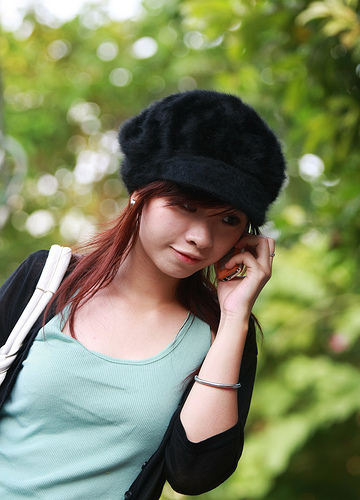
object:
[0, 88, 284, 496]
girl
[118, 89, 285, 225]
hat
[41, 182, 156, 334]
hair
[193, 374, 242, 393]
bracelet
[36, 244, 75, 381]
strap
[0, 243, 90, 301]
shoulder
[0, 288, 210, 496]
shirt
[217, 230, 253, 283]
cellphone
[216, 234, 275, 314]
hand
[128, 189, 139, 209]
earring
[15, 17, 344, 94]
trees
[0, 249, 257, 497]
sweater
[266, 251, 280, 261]
ring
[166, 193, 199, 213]
eyes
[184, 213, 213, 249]
nose